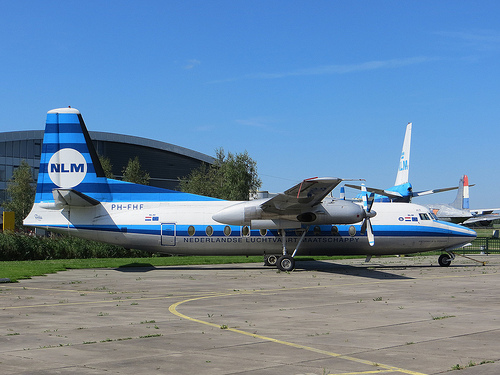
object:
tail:
[32, 105, 113, 189]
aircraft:
[19, 104, 479, 272]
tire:
[275, 254, 297, 273]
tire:
[264, 250, 280, 267]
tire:
[436, 252, 455, 269]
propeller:
[357, 184, 382, 250]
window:
[186, 223, 196, 238]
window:
[204, 225, 214, 237]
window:
[222, 224, 233, 238]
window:
[240, 225, 251, 239]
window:
[347, 224, 358, 236]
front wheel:
[436, 252, 451, 266]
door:
[159, 219, 178, 248]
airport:
[0, 102, 499, 374]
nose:
[411, 216, 485, 256]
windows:
[1, 165, 14, 183]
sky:
[0, 0, 500, 104]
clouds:
[0, 2, 498, 97]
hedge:
[179, 145, 263, 201]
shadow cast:
[260, 254, 419, 280]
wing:
[248, 173, 345, 231]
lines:
[161, 277, 427, 374]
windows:
[418, 211, 432, 221]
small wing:
[45, 185, 99, 206]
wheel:
[437, 255, 450, 267]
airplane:
[342, 120, 476, 202]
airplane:
[428, 171, 500, 227]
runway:
[0, 257, 499, 375]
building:
[0, 130, 246, 206]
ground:
[2, 258, 495, 359]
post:
[0, 197, 11, 244]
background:
[1, 25, 499, 176]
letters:
[108, 201, 145, 212]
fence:
[462, 234, 499, 255]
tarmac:
[0, 284, 500, 375]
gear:
[266, 221, 317, 255]